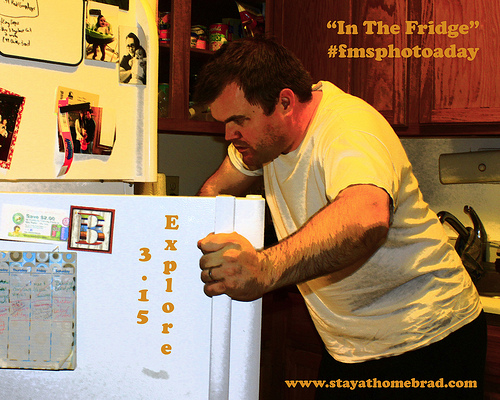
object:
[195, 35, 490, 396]
man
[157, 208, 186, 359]
letters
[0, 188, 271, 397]
door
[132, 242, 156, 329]
numbers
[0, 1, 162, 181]
refrigerator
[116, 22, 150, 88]
photos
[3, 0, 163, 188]
door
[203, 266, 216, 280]
ring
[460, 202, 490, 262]
knives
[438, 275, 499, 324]
counter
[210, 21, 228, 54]
food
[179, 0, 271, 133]
cabinet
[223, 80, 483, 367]
t shirt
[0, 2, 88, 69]
board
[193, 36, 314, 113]
hair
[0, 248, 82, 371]
calendar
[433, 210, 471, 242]
faucet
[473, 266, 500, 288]
sink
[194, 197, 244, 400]
handle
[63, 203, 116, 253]
magnet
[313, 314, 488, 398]
pants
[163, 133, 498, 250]
wall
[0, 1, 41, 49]
writing